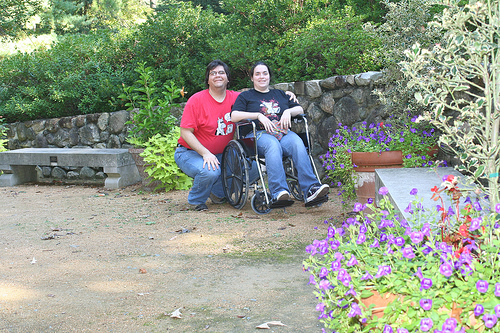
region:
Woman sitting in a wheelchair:
[219, 59, 333, 214]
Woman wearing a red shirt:
[174, 55, 242, 156]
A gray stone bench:
[0, 143, 143, 191]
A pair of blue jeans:
[248, 126, 320, 191]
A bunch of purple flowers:
[300, 182, 496, 327]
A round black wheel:
[219, 137, 251, 209]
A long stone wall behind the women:
[3, 69, 403, 183]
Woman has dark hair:
[201, 56, 232, 92]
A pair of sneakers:
[271, 180, 332, 211]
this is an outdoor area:
[20, 29, 469, 326]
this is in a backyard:
[6, 1, 437, 323]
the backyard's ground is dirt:
[19, 212, 214, 328]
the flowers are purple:
[318, 227, 484, 332]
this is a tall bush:
[118, 72, 179, 162]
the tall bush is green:
[134, 65, 184, 159]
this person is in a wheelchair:
[240, 89, 315, 191]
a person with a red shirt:
[173, 86, 253, 159]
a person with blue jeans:
[169, 142, 259, 214]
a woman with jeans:
[242, 127, 322, 195]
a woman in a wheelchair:
[222, 62, 330, 217]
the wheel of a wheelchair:
[215, 141, 252, 211]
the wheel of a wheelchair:
[250, 189, 275, 214]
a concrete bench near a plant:
[1, 144, 151, 192]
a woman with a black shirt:
[230, 89, 307, 135]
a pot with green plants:
[116, 63, 186, 193]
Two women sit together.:
[175, 59, 328, 210]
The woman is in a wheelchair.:
[225, 63, 325, 208]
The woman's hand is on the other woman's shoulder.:
[282, 89, 301, 105]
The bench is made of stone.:
[0, 148, 140, 189]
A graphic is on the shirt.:
[260, 98, 280, 112]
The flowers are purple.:
[305, 226, 339, 256]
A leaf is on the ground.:
[255, 320, 287, 328]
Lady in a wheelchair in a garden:
[218, 45, 324, 226]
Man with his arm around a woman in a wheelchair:
[141, 20, 356, 205]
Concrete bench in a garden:
[0, 3, 186, 205]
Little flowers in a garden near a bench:
[327, 83, 488, 330]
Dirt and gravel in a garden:
[5, 131, 486, 329]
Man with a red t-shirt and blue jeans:
[148, 36, 243, 213]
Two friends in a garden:
[150, 11, 453, 328]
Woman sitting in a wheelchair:
[225, 45, 351, 215]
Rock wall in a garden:
[0, 72, 176, 243]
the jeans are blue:
[244, 128, 321, 190]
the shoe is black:
[303, 182, 333, 207]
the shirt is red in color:
[176, 88, 239, 155]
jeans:
[173, 144, 230, 206]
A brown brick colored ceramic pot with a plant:
[348, 147, 429, 199]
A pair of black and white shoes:
[276, 185, 325, 200]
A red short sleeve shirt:
[182, 91, 241, 150]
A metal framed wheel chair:
[218, 114, 320, 211]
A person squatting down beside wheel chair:
[180, 63, 237, 207]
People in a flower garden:
[174, 59, 329, 211]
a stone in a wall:
[287, 78, 307, 94]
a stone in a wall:
[301, 77, 323, 101]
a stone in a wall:
[321, 71, 336, 86]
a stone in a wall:
[332, 73, 357, 83]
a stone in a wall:
[355, 66, 375, 83]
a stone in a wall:
[362, 90, 388, 116]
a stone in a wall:
[327, 96, 360, 119]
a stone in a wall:
[310, 101, 326, 127]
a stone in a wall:
[315, 114, 337, 150]